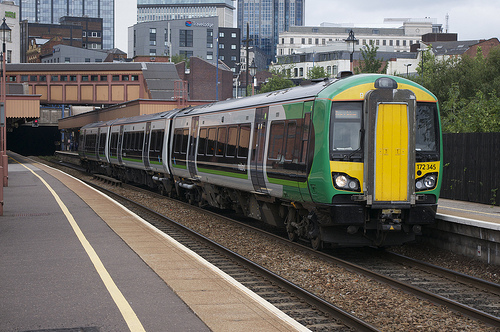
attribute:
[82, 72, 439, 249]
train — green, yellow, yel, white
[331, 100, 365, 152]
window — tinted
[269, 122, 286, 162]
window — tinted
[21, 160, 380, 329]
track — black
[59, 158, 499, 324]
track — black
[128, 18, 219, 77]
building — large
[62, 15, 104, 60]
building — large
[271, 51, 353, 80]
building — large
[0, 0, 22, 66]
building — large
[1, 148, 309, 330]
platform — black, yellow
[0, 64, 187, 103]
bridge — large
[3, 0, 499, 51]
sky — blue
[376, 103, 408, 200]
door — yellow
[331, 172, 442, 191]
headlights — slanted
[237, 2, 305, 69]
skyscraper — tall, distance